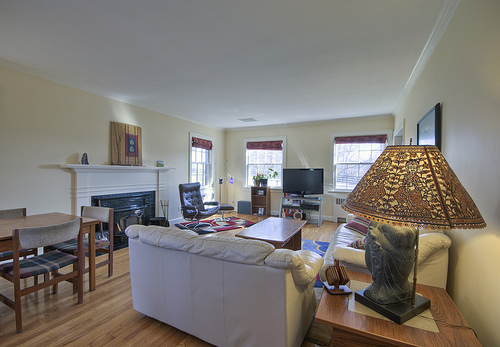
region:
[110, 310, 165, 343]
A smooth brown wood floor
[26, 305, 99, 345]
A smooth brown wood floor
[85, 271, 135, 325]
A smooth brown wood floor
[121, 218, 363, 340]
A white leather coach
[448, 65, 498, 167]
A white house wall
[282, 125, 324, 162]
A white house wall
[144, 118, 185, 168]
A white house wall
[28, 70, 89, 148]
A white house wall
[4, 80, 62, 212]
A white house wall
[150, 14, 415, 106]
A white house ceiling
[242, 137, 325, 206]
a window beside the television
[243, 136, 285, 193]
green plants kept in front of the window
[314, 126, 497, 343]
an electric lamp in a table near the wall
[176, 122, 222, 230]
a chair near the wall beside the window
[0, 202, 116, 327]
a dining table with chairs around it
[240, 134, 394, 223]
a television on the table in between the windows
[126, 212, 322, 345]
a table in front of the couch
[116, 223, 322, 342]
a couch on the wooden floor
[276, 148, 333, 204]
a television kept in front of the wall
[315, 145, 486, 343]
an electric lamp glowing on the table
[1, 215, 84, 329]
a plaid wooden chair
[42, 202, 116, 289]
a plaid wooden chair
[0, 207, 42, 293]
a plaid wooden chair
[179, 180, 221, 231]
a black chair on a carpet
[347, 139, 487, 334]
a lamp on a figurine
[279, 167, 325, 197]
a television at the end of the room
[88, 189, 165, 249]
an engraved black fireplace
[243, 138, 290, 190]
a window at the end of the room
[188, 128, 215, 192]
a window at the end of the room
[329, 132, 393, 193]
a window at the end of the room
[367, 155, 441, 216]
lamp shade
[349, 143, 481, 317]
a lamp on the table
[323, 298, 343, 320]
the table is brown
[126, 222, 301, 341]
the couch that is white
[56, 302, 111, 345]
the wooden floor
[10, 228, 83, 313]
a chair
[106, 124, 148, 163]
a picture on the wall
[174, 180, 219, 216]
a black chair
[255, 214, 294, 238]
a coffee table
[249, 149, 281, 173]
a window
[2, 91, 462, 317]
a living room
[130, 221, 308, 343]
a white couch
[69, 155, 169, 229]
a fireplace on the wall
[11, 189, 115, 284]
a table and chairs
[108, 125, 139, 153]
a painting on the mantle of the fireplace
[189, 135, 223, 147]
red curtains above the window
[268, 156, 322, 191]
a black television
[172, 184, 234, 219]
a chair in the room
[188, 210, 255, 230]
a rug on the floor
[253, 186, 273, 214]
a book shelf